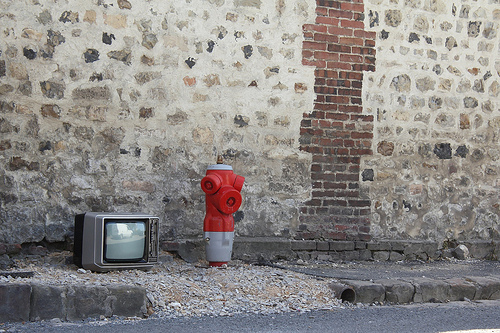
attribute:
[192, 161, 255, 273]
hydrant — red, grey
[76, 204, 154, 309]
television — small, old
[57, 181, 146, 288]
television — small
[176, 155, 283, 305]
hydrant — red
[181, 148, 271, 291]
hydrant — red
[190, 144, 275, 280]
hydrant — red, grey